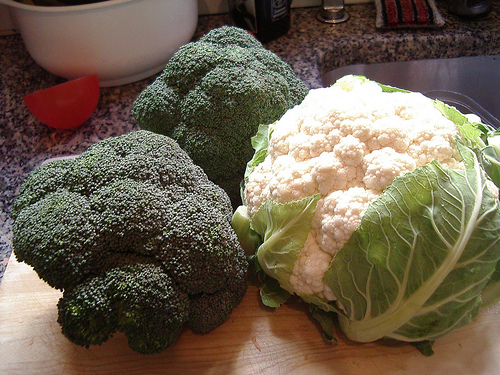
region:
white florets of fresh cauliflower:
[236, 72, 483, 297]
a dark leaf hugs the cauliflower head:
[325, 154, 499, 340]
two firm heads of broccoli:
[11, 12, 298, 351]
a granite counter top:
[0, 5, 497, 257]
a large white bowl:
[1, 0, 202, 82]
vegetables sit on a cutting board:
[1, 236, 498, 373]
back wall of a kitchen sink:
[312, 49, 497, 129]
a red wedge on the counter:
[21, 60, 115, 131]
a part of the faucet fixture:
[320, 0, 347, 25]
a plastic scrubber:
[369, 0, 448, 37]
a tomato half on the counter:
[21, 75, 101, 130]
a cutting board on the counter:
[0, 229, 498, 371]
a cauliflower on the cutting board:
[232, 67, 497, 364]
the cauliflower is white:
[248, 78, 462, 291]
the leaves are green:
[328, 147, 497, 352]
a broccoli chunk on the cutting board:
[7, 123, 253, 353]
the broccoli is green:
[14, 128, 252, 360]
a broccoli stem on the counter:
[135, 23, 307, 187]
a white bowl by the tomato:
[3, 1, 198, 98]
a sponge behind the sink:
[377, 0, 461, 33]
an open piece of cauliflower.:
[228, 47, 498, 350]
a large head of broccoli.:
[5, 115, 254, 363]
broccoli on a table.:
[129, 25, 323, 212]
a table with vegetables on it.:
[0, 237, 497, 373]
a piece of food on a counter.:
[17, 65, 109, 136]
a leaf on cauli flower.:
[333, 153, 491, 343]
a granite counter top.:
[199, 1, 497, 54]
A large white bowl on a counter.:
[3, 0, 213, 93]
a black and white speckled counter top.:
[0, 39, 335, 276]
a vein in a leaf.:
[332, 151, 490, 347]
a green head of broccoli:
[7, 128, 252, 356]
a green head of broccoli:
[121, 24, 316, 198]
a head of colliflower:
[233, 63, 495, 349]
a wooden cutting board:
[21, 134, 483, 365]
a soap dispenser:
[319, 1, 355, 27]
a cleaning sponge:
[376, 1, 443, 40]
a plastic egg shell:
[8, 55, 123, 140]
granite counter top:
[6, 13, 489, 273]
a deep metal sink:
[320, 43, 485, 104]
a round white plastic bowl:
[11, 2, 218, 88]